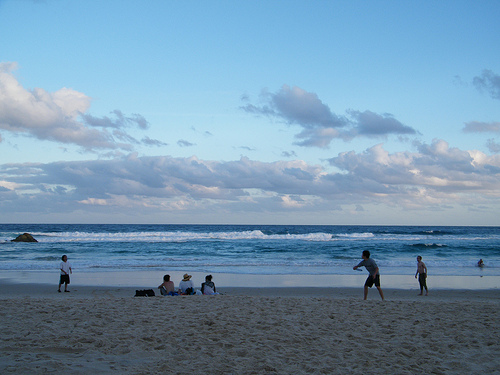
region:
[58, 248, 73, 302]
person on sandy beach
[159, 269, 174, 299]
person on sandy beach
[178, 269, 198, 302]
person on sandy beach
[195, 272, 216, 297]
person on sandy beach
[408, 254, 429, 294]
person on sandy beach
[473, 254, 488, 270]
person in water near sandy beach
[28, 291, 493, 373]
sandy beach in foreground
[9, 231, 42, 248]
large rocks in water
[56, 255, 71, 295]
PERSON ON SANDY BEACH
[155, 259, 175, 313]
PERSON ON SANDY BEACH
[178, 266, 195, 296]
PERSON ON SANDY BEACH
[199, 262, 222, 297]
PERSON ON SANDY BEACH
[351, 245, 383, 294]
PERSON ON SANDY BEACH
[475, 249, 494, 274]
PERSON SWIMMING NEAR SANDY BEACH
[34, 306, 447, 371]
SANDY BEACH IN FOREGROUND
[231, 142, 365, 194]
WHTIE CLOUDS IN SKY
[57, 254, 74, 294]
young man wearing white shirt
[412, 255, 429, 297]
man standing on the sand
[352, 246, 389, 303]
man holding a frisbee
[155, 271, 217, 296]
three people sitting on the sand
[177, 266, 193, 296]
person wearing a hat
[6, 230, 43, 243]
big stone next to shore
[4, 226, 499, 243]
waves on the water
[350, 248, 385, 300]
man wearing dark shorts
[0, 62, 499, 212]
clouds in the sky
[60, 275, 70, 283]
man wearing black color short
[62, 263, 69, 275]
man wearing white color tees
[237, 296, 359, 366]
brown sand at shore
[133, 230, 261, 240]
white waves on water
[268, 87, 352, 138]
white cloud in blue sky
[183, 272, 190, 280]
man wearing hat sitting on sand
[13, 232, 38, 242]
rock immersed in water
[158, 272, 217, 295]
three person sitting on sand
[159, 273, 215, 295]
three people sitting on the beach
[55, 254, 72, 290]
person wearing white shirt and black shorts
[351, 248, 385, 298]
man throwing a white frisbee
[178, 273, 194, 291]
woman sitting on the beach wearing hat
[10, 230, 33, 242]
rock jutting out of the water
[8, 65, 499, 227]
clouds above the water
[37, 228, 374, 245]
waves crashing in the ocean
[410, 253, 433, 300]
person standing by the water's edge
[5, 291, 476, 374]
tracks in the sand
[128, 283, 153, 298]
bag next to three people sitting on the beach